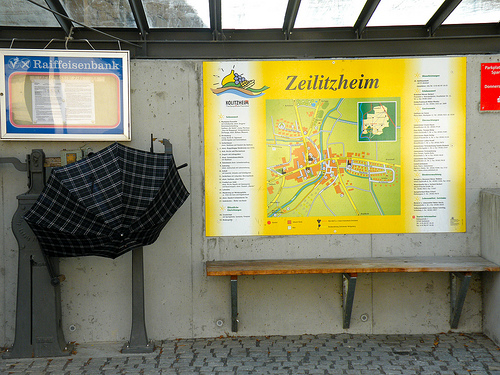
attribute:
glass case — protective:
[6, 45, 143, 140]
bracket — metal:
[226, 274, 244, 332]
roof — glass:
[4, 3, 497, 50]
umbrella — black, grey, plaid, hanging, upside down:
[19, 151, 194, 251]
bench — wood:
[182, 235, 493, 282]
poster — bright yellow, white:
[201, 57, 471, 238]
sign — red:
[477, 59, 498, 111]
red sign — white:
[480, 61, 498, 112]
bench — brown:
[163, 232, 494, 309]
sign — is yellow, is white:
[203, 59, 468, 236]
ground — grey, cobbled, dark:
[1, 333, 498, 373]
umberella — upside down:
[25, 140, 209, 297]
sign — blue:
[6, 66, 129, 139]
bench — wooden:
[203, 254, 499, 331]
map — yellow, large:
[196, 56, 470, 236]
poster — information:
[4, 55, 126, 137]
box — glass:
[0, 48, 134, 143]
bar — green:
[449, 270, 476, 331]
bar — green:
[337, 268, 357, 330]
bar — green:
[227, 277, 239, 331]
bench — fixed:
[201, 173, 495, 281]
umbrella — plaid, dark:
[21, 142, 190, 257]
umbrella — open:
[20, 128, 190, 280]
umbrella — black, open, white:
[18, 127, 233, 311]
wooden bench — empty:
[198, 249, 497, 335]